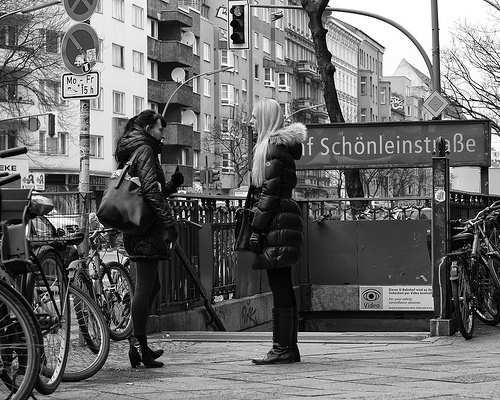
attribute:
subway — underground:
[134, 162, 452, 341]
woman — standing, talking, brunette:
[93, 105, 184, 369]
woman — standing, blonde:
[230, 98, 311, 367]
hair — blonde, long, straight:
[248, 98, 283, 188]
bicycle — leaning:
[445, 204, 500, 340]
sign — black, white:
[61, 71, 102, 101]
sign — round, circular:
[60, 22, 101, 76]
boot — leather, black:
[251, 304, 297, 366]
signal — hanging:
[226, 3, 254, 53]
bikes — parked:
[0, 145, 138, 399]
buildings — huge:
[1, 0, 386, 254]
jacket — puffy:
[248, 121, 309, 271]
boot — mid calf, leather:
[126, 332, 166, 372]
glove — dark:
[168, 164, 187, 188]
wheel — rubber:
[450, 259, 477, 343]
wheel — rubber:
[89, 260, 137, 345]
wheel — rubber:
[23, 246, 72, 396]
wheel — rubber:
[18, 276, 112, 386]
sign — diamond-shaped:
[420, 91, 449, 119]